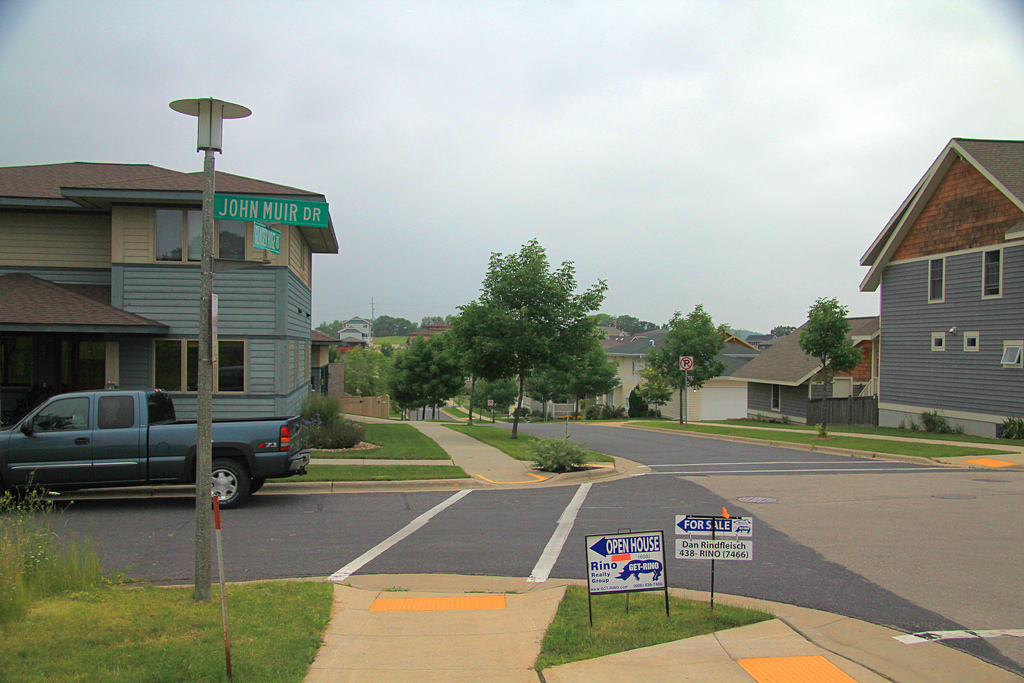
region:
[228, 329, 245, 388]
window on the building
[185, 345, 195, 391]
window on the building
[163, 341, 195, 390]
window on the building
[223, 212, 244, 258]
window on the building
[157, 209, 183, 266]
window on the building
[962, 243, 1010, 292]
window on the building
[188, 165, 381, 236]
John Muir street sign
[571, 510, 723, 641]
open house sign with two posts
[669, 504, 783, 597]
For sale sign on the corner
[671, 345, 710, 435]
no parking sign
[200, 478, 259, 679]
orange and white post in the ground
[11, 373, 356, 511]
blue truck parked on the street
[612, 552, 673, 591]
Rhino on the open house sign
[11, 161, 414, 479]
tan and blue house behind the truck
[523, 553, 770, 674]
triangular patch of grass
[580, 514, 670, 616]
blue and white sign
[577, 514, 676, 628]
open house sign on the lawn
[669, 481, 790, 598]
for sale sign on the grass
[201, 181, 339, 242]
green street sign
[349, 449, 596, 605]
white lines in the street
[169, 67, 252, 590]
street light on wooden pole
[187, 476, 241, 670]
metal pole with red on top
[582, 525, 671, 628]
Open house sign on the sidewalk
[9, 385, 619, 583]
Truck on the side of the road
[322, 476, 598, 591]
Pedestrian crossing is empty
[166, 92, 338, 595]
Post with light and street signs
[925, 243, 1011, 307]
Two windows on the side of the wall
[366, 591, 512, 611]
Rectangular yellow paint on the sidewalk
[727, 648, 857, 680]
Rectangular yellow paint on the sidewalk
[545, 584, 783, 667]
trimmed green grass triangle shaped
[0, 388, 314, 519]
dark blue pickup truck is parked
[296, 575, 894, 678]
orange paint square on sidewalk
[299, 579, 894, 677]
sidewalk is gray concrete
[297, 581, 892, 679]
gray side walk next to triangle patch grass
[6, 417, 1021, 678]
white painted line on street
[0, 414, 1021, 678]
black paved asphalt street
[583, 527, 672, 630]
sign is blue and white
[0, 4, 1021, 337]
cloudy gray gloomy sky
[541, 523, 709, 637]
Open house sign on the edge of the grass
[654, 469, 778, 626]
For sale sign on the corner of the intersection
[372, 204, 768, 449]
Many trees lined along the side of the street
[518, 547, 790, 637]
Patch of grass on the corner of the street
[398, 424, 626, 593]
White lines indicating the area for the crosswalk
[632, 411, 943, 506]
White lines on the street for the crosswalk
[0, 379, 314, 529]
a dark grey truck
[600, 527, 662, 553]
the words open house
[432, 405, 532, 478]
a concrete walk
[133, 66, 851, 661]
this is a suburban area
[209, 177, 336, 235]
a green and white street sign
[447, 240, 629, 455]
a large green tree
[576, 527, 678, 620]
a black, white and blue sign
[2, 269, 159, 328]
the roof of a home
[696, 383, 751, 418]
a white garage door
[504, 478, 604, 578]
a long white painted line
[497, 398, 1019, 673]
a paved road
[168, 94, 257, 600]
a tall gray light pole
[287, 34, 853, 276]
clouds in the sky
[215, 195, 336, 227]
a green street sign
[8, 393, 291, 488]
a grey truck on the street